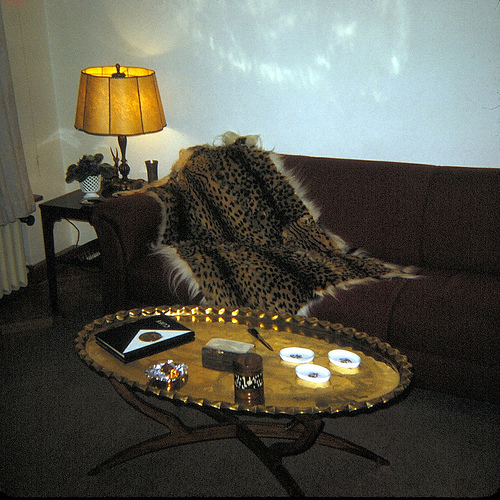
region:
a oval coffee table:
[76, 300, 414, 421]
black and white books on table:
[96, 310, 191, 360]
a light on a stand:
[75, 60, 165, 197]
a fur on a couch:
[160, 130, 405, 305]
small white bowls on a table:
[280, 340, 365, 402]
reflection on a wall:
[236, 10, 421, 117]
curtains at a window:
[0, 85, 40, 300]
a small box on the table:
[201, 332, 246, 372]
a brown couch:
[90, 165, 497, 296]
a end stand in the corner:
[41, 162, 124, 319]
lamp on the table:
[62, 60, 149, 187]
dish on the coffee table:
[324, 345, 361, 372]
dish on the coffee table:
[289, 366, 328, 384]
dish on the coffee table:
[278, 343, 318, 360]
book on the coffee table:
[101, 320, 191, 354]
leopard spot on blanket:
[266, 180, 273, 190]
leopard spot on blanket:
[268, 285, 279, 299]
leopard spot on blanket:
[207, 284, 221, 296]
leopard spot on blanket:
[185, 271, 199, 283]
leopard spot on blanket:
[280, 291, 290, 303]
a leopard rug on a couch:
[122, 136, 408, 321]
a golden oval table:
[73, 304, 413, 497]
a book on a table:
[96, 312, 195, 360]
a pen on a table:
[246, 323, 271, 352]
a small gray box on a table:
[202, 335, 254, 373]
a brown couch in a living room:
[88, 149, 498, 401]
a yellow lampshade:
[74, 65, 165, 138]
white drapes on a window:
[1, 14, 37, 223]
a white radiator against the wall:
[1, 221, 33, 296]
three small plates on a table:
[281, 344, 358, 381]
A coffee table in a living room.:
[66, 302, 432, 495]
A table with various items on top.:
[65, 300, 410, 495]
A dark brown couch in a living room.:
[85, 136, 492, 402]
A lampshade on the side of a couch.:
[75, 60, 168, 197]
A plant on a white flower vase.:
[61, 152, 106, 201]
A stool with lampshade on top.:
[37, 61, 168, 314]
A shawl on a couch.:
[127, 124, 412, 329]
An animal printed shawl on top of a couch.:
[139, 132, 422, 329]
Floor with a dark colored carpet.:
[3, 267, 488, 498]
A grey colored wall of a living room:
[48, 4, 498, 199]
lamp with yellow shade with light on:
[74, 63, 168, 138]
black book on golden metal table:
[94, 313, 191, 361]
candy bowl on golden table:
[146, 359, 191, 390]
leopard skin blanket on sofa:
[164, 137, 352, 298]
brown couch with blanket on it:
[317, 159, 431, 289]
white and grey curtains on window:
[5, 122, 26, 289]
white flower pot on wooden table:
[71, 152, 110, 202]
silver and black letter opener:
[243, 320, 275, 350]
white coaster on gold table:
[327, 346, 361, 373]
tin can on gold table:
[232, 352, 267, 402]